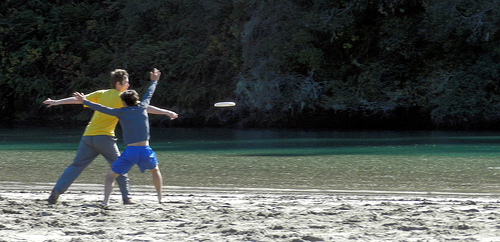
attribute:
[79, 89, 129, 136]
shirt — yellow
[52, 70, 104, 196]
man — yellow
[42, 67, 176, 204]
guy — taller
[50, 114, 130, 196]
pants — gray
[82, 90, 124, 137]
shirt — yellow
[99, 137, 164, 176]
shorts — blue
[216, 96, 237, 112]
frisbee — white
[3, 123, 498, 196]
water — green, brown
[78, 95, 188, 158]
shirt — gray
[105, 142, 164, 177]
shorts — blue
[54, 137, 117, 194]
pants — gray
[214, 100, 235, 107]
frisbee — white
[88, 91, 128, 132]
shirt — yellow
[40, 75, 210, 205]
boy — gray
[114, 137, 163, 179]
shorts — blue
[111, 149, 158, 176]
shorts — blue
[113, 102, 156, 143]
shirt — blue, long sleeve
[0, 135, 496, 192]
water —  still 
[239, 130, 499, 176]
water — teal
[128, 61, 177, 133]
arm — outstretched